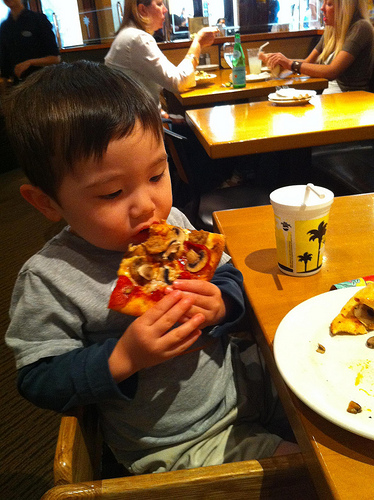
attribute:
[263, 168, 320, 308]
cup — yellow, small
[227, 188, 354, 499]
table — wood, wooden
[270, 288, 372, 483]
plate — white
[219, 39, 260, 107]
bottle — green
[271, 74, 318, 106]
plates — stacked, piled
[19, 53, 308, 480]
boy — eating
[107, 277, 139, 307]
pepperoni — sliced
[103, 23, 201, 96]
shirt — white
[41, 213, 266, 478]
shirt — grey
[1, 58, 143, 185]
hair — dark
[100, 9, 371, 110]
women — sitting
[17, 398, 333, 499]
high chair — wooden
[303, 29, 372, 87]
shirt — brown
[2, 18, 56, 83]
shirt — black